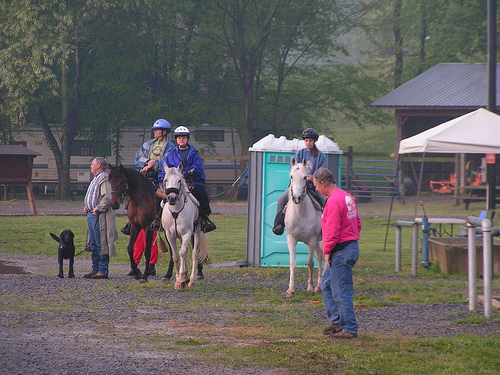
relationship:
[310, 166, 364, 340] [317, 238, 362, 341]
man wearing jeans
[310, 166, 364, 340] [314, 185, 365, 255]
man wearing shirt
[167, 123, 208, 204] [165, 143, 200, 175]
woman with jacket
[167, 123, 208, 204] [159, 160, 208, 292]
woman riding white horse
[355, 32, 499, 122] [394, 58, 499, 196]
roof on building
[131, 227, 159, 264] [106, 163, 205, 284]
fabric on horse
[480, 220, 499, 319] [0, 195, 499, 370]
poles on ground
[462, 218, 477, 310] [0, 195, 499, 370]
poles on ground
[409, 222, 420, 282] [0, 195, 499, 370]
poles on ground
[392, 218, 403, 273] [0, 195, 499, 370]
poles on ground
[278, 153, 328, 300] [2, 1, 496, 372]
white horse at park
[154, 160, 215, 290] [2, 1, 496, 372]
white horse at park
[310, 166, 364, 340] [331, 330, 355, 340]
man wears shoe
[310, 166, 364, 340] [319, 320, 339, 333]
man wears shoe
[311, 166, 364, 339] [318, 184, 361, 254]
man wears shirt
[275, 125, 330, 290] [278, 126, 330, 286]
girl rides horse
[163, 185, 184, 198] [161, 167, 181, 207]
fabric around horse's face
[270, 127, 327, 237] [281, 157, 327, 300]
girl on white horse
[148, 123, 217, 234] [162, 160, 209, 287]
woman on horse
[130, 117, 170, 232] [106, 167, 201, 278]
rider on horse